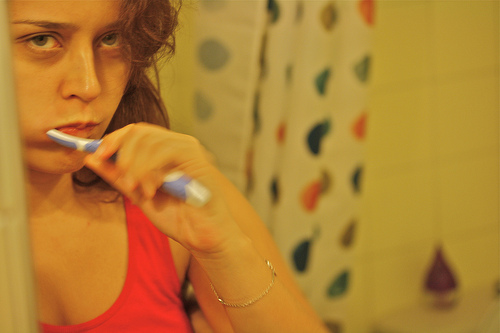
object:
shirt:
[33, 193, 192, 331]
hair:
[70, 0, 182, 203]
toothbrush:
[45, 127, 210, 204]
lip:
[54, 121, 99, 134]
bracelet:
[210, 259, 276, 308]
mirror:
[0, 2, 500, 333]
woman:
[0, 0, 332, 333]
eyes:
[13, 30, 123, 51]